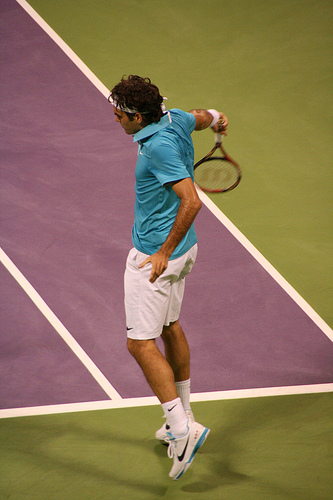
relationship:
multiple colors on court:
[3, 5, 221, 65] [17, 8, 288, 251]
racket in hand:
[186, 107, 237, 203] [199, 109, 239, 137]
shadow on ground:
[145, 347, 315, 500] [12, 246, 324, 496]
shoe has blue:
[150, 404, 248, 474] [189, 423, 222, 467]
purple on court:
[10, 137, 114, 275] [17, 8, 288, 251]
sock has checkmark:
[152, 395, 185, 441] [159, 390, 184, 419]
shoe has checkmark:
[150, 404, 248, 474] [172, 432, 193, 468]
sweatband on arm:
[202, 91, 225, 133] [171, 106, 239, 134]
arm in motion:
[171, 106, 239, 134] [154, 91, 260, 148]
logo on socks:
[150, 401, 182, 415] [166, 393, 179, 445]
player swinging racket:
[59, 28, 254, 493] [186, 107, 237, 203]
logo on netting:
[197, 164, 245, 189] [197, 159, 232, 187]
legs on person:
[89, 324, 214, 396] [59, 28, 254, 493]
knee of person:
[112, 332, 153, 370] [59, 28, 254, 493]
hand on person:
[139, 246, 172, 284] [59, 28, 254, 493]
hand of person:
[139, 246, 172, 284] [59, 28, 254, 493]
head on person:
[74, 36, 173, 150] [59, 28, 254, 493]